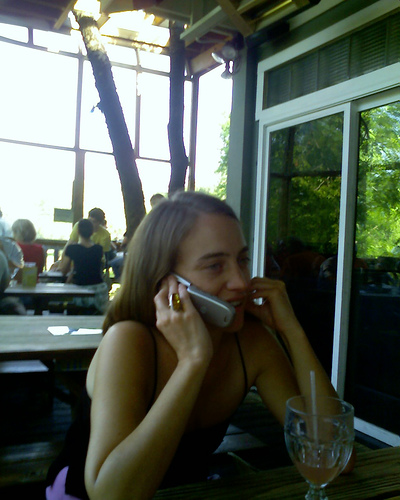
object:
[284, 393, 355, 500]
glass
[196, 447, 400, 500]
table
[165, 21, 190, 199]
trunk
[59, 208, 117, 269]
people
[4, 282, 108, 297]
table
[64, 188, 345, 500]
girl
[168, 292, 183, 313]
ring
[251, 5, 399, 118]
windows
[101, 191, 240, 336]
hair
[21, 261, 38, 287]
container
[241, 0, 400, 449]
door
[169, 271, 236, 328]
cell phone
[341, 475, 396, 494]
grain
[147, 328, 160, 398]
straps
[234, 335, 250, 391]
straps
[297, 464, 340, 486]
liquid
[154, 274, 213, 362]
hand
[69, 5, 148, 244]
tree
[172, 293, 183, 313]
stone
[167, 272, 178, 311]
finger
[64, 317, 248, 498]
shirt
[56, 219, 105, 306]
lady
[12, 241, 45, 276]
shirt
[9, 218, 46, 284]
person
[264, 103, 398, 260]
reflection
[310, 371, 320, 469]
straw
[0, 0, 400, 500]
building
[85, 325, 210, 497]
arm